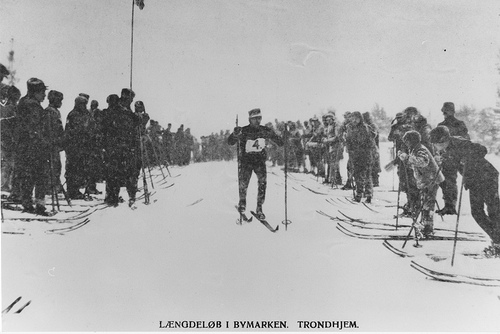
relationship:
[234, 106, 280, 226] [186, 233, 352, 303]
man skiing on top of snow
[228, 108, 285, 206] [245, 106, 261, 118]
man wearing hat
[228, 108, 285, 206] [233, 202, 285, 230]
man wearing skis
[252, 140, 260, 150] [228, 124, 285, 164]
4 attached to jacket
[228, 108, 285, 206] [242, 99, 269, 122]
man wearing hat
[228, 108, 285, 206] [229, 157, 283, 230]
man wearing pants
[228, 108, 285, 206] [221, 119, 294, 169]
man wearing jacket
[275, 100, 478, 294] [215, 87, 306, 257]
people watching skier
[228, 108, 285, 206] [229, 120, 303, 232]
man on skis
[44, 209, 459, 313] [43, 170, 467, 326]
snow on ground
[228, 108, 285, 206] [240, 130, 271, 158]
man wearing sign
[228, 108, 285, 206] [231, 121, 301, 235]
man holding poles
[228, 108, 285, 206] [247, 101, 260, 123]
man wearing hat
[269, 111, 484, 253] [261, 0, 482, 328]
people standing on side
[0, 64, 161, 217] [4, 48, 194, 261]
group standing on side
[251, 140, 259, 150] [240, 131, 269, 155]
4 on sign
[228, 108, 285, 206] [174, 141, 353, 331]
man on slope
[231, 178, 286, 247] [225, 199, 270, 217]
skis on feet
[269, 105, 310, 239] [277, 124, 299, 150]
pole in hand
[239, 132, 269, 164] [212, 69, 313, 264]
bib on skier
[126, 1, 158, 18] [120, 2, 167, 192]
flag on flagpole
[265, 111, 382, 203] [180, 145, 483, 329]
people in snow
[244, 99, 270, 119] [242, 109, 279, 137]
hat on head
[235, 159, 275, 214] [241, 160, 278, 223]
pants on legs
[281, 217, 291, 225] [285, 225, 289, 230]
ring around pole tip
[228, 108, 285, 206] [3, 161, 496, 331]
man on slope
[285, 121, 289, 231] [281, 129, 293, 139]
pole in hand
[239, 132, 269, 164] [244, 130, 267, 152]
bib on skier's chest